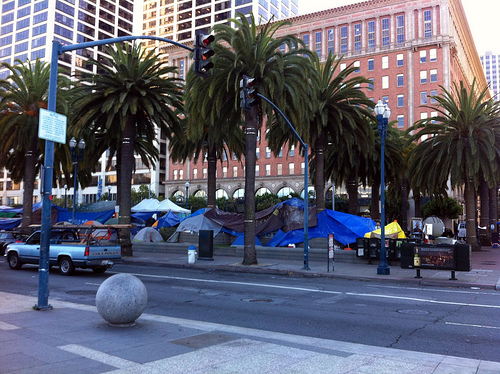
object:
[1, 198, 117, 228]
tarp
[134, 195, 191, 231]
tarp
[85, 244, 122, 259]
back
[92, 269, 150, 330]
ball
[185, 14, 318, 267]
palm tree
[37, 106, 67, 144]
sign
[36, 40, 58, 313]
traffic pole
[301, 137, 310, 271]
traffic pole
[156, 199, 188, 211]
white tents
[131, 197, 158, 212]
white tents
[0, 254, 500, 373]
ground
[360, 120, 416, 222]
tree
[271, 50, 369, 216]
tree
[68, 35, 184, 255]
tree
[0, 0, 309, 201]
buildings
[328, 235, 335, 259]
sign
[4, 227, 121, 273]
truck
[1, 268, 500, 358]
street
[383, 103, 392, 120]
streetlight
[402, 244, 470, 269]
ad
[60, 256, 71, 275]
tire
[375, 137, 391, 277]
pole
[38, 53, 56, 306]
pole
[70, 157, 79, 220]
pole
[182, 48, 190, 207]
pole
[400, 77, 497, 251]
palm tree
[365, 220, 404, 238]
tent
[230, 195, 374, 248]
tent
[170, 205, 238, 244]
tent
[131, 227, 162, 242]
tent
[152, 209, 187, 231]
tent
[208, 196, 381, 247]
tarp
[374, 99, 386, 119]
street light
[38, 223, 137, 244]
ladder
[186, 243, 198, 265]
fire hydrant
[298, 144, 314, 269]
pole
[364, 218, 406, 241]
tarp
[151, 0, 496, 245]
building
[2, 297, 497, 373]
sidewalk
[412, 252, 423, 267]
bottle